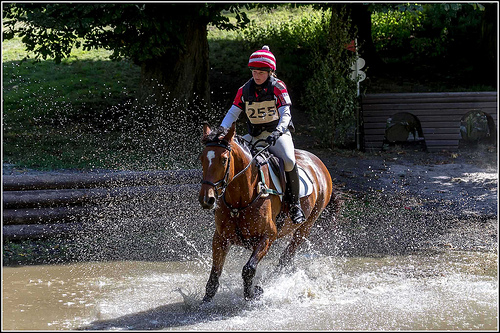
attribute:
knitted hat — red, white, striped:
[238, 40, 279, 75]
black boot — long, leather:
[281, 157, 314, 225]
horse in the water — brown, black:
[187, 116, 337, 309]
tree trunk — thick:
[134, 25, 214, 112]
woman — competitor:
[220, 43, 300, 223]